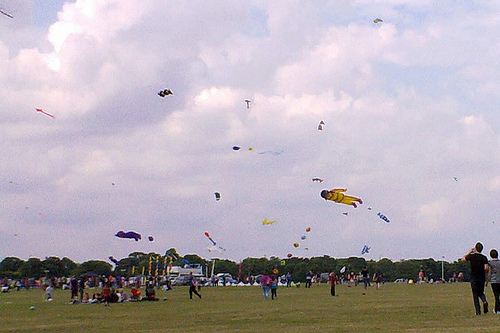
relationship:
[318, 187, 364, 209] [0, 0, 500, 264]
kite flying in sky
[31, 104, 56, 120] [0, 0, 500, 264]
kite flying in sky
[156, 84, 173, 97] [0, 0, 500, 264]
kite flying in sky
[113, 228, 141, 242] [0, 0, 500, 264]
kite flying in sky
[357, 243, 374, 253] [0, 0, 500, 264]
kite flying in sky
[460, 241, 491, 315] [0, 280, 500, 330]
guy walking in field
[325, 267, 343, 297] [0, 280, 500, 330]
man walking in field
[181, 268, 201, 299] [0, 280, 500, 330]
man walking in field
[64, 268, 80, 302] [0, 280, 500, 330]
man walking in field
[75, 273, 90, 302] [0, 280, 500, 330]
man walking in field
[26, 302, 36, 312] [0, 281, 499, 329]
ball on ground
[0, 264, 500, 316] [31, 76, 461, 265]
people watching kites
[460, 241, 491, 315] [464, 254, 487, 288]
guy wearing a shirt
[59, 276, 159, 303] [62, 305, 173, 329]
people gathered on grass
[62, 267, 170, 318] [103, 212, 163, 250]
people flying a kite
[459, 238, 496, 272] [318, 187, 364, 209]
couple watching kite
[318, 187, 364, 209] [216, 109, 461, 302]
kite in sky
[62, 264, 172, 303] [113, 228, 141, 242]
group flying kite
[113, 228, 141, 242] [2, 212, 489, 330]
kite in a park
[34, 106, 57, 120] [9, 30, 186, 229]
kite flying in sky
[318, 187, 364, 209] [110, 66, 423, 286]
kite in sky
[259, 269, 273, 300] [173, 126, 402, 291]
people outside flying kites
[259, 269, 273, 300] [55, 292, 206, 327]
people sitting on grass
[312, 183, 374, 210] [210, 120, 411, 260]
kite in sky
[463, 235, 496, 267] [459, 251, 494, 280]
guy wearing shirt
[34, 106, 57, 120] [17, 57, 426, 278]
kite flying high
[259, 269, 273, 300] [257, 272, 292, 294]
people with shirt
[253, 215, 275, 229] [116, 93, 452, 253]
kite in sky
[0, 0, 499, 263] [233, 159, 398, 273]
clouds and kites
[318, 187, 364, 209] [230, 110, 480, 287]
kite in sky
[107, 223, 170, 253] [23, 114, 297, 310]
kite in sky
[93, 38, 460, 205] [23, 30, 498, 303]
clouds in a sky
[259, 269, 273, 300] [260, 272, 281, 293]
people in a shirt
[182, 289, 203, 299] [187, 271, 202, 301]
pants on a man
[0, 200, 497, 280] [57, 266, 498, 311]
tree line behind people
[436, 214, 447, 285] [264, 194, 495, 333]
pole in field